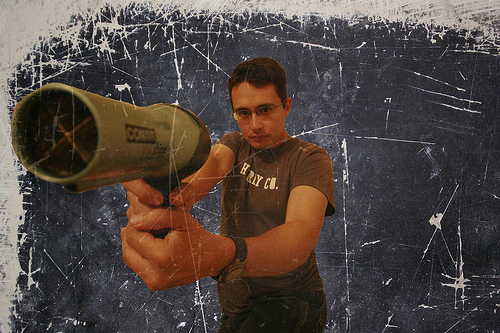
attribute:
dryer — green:
[12, 81, 212, 191]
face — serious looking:
[229, 82, 284, 146]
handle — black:
[146, 183, 172, 239]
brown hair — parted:
[229, 55, 287, 111]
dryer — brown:
[19, 83, 206, 206]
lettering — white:
[234, 163, 279, 193]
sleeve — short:
[289, 143, 335, 213]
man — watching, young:
[113, 49, 349, 331]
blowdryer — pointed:
[10, 83, 213, 240]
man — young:
[122, 53, 339, 327]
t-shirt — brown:
[211, 131, 340, 311]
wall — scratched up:
[64, 11, 479, 79]